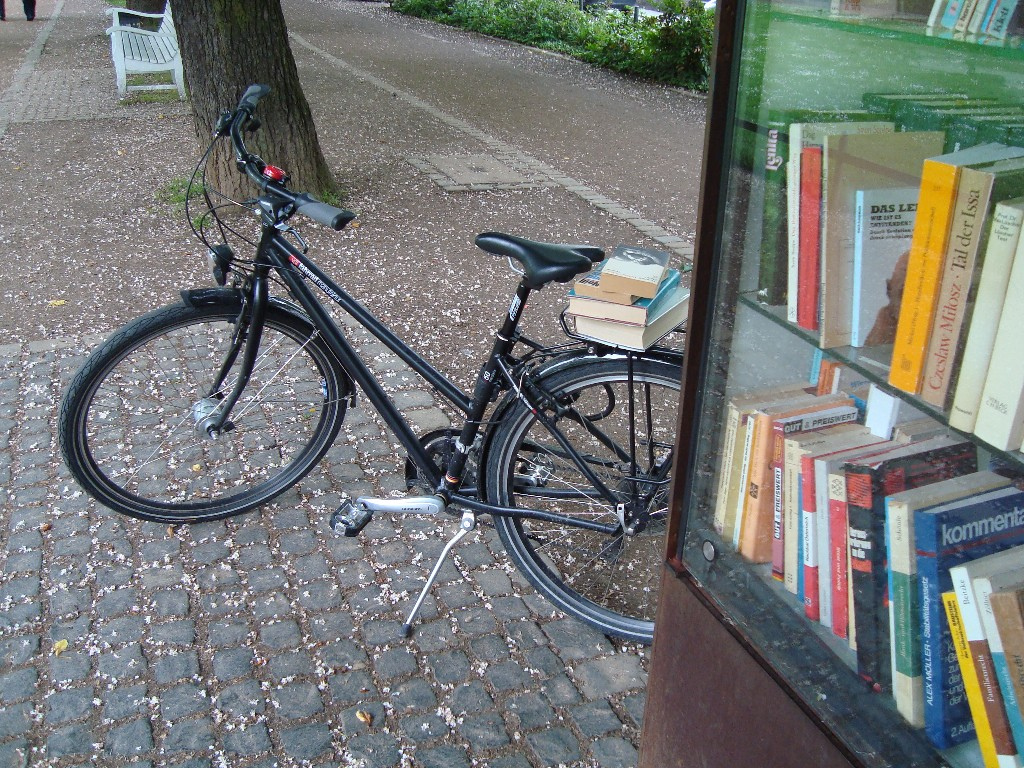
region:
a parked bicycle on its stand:
[59, 87, 679, 644]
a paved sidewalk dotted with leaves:
[4, 1, 710, 767]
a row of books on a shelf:
[709, 387, 1019, 758]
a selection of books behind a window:
[674, 0, 1022, 763]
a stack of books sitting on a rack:
[557, 248, 688, 369]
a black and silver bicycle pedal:
[333, 495, 447, 541]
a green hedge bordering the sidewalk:
[394, 4, 720, 94]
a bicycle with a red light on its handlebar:
[58, 84, 684, 651]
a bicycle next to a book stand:
[62, 0, 1020, 767]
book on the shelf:
[988, 600, 1021, 673]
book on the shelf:
[808, 571, 854, 657]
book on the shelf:
[789, 287, 863, 336]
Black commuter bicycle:
[67, 83, 694, 652]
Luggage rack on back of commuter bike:
[544, 243, 697, 544]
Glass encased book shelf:
[636, 0, 998, 760]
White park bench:
[103, 1, 183, 101]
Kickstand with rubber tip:
[392, 499, 485, 646]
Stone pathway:
[14, 23, 686, 754]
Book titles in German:
[706, 377, 1020, 741]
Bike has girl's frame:
[261, 221, 509, 525]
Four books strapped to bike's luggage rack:
[552, 238, 699, 353]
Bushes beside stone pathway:
[378, 0, 720, 98]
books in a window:
[823, 453, 871, 662]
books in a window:
[768, 430, 808, 589]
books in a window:
[961, 198, 1018, 432]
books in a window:
[882, 143, 959, 381]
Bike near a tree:
[59, 91, 712, 648]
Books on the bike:
[555, 260, 683, 347]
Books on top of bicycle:
[572, 258, 675, 353]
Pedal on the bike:
[318, 483, 445, 547]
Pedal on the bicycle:
[322, 477, 455, 548]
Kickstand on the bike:
[388, 503, 481, 644]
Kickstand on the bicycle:
[391, 471, 487, 661]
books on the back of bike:
[576, 204, 688, 364]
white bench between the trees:
[96, 4, 197, 105]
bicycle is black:
[64, 104, 683, 657]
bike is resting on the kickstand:
[371, 522, 488, 633]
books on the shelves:
[703, 85, 1020, 766]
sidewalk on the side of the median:
[431, 30, 701, 176]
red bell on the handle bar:
[254, 162, 285, 197]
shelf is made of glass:
[744, 280, 1022, 536]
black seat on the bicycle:
[460, 226, 602, 283]